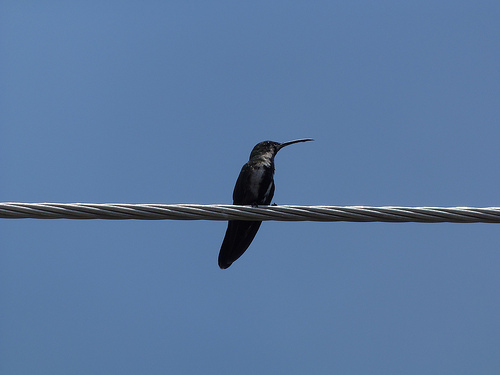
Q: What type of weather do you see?
A: It is cloudless.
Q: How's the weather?
A: It is cloudless.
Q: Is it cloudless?
A: Yes, it is cloudless.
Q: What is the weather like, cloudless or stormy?
A: It is cloudless.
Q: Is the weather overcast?
A: No, it is cloudless.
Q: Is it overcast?
A: No, it is cloudless.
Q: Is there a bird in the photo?
A: Yes, there is a bird.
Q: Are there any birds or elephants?
A: Yes, there is a bird.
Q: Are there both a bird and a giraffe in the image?
A: No, there is a bird but no giraffes.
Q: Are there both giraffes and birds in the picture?
A: No, there is a bird but no giraffes.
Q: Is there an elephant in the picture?
A: No, there are no elephants.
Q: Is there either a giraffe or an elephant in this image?
A: No, there are no elephants or giraffes.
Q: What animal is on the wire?
A: The bird is on the wire.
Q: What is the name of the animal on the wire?
A: The animal is a bird.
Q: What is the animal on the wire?
A: The animal is a bird.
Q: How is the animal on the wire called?
A: The animal is a bird.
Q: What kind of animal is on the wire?
A: The animal is a bird.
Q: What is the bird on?
A: The bird is on the wire.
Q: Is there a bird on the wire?
A: Yes, there is a bird on the wire.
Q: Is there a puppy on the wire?
A: No, there is a bird on the wire.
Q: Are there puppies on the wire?
A: No, there is a bird on the wire.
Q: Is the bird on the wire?
A: Yes, the bird is on the wire.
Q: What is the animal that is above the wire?
A: The animal is a bird.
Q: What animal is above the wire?
A: The animal is a bird.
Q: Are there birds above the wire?
A: Yes, there is a bird above the wire.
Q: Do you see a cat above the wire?
A: No, there is a bird above the wire.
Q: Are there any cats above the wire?
A: No, there is a bird above the wire.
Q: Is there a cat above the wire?
A: No, there is a bird above the wire.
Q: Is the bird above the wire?
A: Yes, the bird is above the wire.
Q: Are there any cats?
A: No, there are no cats.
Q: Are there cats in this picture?
A: No, there are no cats.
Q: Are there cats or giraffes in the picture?
A: No, there are no cats or giraffes.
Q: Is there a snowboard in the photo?
A: No, there are no snowboards.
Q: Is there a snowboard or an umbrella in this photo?
A: No, there are no snowboards or umbrellas.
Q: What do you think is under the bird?
A: The wire is under the bird.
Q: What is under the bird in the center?
A: The wire is under the bird.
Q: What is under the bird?
A: The wire is under the bird.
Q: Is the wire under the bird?
A: Yes, the wire is under the bird.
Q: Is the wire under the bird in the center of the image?
A: Yes, the wire is under the bird.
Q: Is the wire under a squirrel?
A: No, the wire is under the bird.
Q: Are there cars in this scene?
A: No, there are no cars.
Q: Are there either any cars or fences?
A: No, there are no cars or fences.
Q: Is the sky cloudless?
A: Yes, the sky is cloudless.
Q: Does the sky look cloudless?
A: Yes, the sky is cloudless.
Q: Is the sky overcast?
A: No, the sky is cloudless.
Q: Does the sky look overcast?
A: No, the sky is cloudless.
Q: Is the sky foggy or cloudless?
A: The sky is cloudless.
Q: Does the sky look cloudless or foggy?
A: The sky is cloudless.